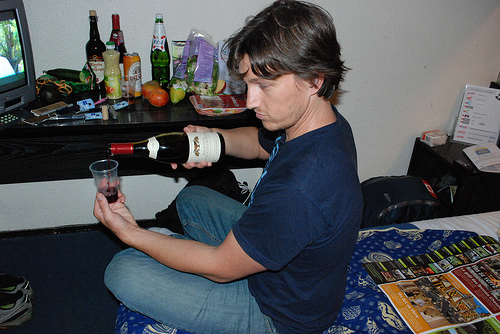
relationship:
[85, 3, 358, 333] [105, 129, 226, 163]
man holding bottle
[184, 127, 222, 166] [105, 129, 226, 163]
label on bottle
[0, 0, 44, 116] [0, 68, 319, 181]
tv on table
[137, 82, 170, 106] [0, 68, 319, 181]
apples on table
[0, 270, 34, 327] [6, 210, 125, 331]
shoes on floor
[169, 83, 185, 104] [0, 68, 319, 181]
pear on table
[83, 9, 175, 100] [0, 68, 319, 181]
bottles on table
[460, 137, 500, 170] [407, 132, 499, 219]
brochure on nightstand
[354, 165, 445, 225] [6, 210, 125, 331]
backpack on floor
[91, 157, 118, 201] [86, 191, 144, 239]
cup in hand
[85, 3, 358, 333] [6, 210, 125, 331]
man on floor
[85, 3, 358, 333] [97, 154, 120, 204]
man pouring wine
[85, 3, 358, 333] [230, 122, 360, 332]
man wearing shirt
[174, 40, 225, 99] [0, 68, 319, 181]
salad on table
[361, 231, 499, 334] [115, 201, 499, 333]
paper on bed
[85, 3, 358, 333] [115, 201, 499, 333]
man on bed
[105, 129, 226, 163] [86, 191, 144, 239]
bottle in hand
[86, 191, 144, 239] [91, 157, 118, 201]
hand holding cup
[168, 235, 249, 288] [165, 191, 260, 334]
elbow on lap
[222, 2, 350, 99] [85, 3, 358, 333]
hair on man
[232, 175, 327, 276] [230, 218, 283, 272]
sleeve has edge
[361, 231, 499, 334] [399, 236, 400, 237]
calendar has part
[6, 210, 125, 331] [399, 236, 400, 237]
floor has part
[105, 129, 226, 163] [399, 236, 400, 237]
bottle has part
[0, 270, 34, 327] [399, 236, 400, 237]
shoes have part